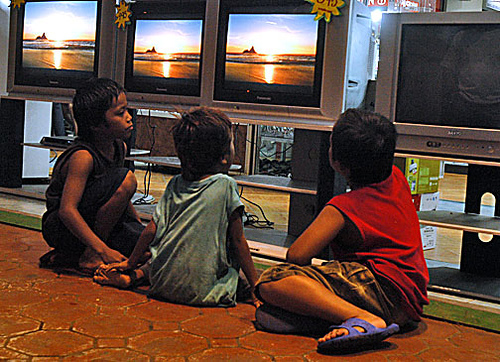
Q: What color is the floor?
A: Brown.